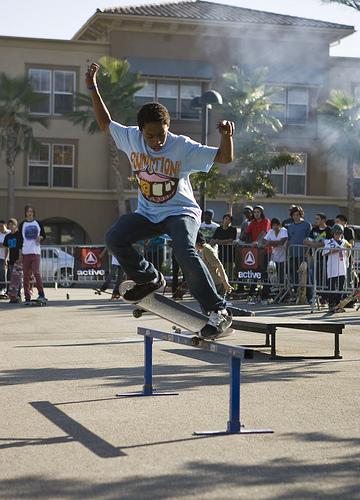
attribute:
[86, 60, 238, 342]
boy — young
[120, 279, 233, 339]
skateboard — black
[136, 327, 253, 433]
ramp — blue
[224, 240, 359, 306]
fence — metal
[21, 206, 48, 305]
man — young, standing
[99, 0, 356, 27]
roof — brown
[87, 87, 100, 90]
wristband — thin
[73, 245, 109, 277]
banner — red, white, black, small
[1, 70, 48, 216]
tree — green, tall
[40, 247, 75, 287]
car — white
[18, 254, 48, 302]
pants — copper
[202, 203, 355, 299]
crowd — watching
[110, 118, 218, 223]
shirt — blue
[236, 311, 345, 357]
table — metal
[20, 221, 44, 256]
shirt — white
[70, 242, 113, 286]
advertisement — active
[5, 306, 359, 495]
court — cement